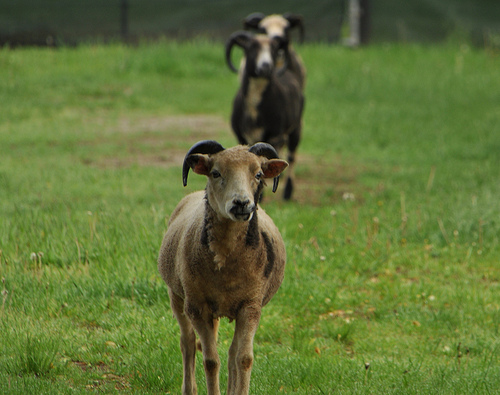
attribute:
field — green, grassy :
[1, 44, 498, 394]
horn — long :
[181, 139, 227, 186]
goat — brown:
[168, 141, 278, 391]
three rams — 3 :
[150, 6, 309, 392]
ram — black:
[224, 28, 306, 215]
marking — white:
[244, 30, 272, 147]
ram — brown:
[149, 133, 289, 393]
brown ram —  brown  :
[147, 132, 323, 392]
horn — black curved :
[170, 136, 233, 205]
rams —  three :
[128, 0, 378, 395]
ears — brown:
[261, 157, 288, 182]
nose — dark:
[233, 197, 253, 207]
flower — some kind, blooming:
[330, 217, 442, 300]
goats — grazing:
[216, 31, 333, 190]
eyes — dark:
[201, 161, 278, 185]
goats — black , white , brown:
[202, 23, 312, 145]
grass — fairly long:
[377, 69, 496, 166]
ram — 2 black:
[220, 28, 308, 199]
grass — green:
[355, 179, 459, 317]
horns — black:
[183, 137, 280, 191]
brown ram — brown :
[156, 140, 289, 394]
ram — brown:
[161, 130, 373, 368]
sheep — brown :
[78, 110, 414, 394]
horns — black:
[149, 128, 333, 391]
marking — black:
[250, 219, 293, 295]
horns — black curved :
[170, 132, 293, 191]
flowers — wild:
[0, 46, 495, 390]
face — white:
[242, 35, 282, 76]